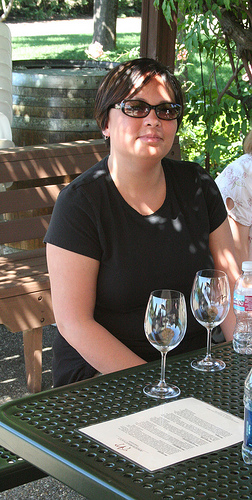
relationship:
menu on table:
[78, 393, 244, 477] [0, 333, 251, 497]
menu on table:
[78, 393, 244, 477] [52, 378, 113, 440]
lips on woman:
[138, 133, 173, 148] [50, 65, 231, 397]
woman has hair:
[46, 56, 249, 370] [93, 53, 186, 129]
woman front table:
[46, 56, 249, 370] [0, 333, 251, 497]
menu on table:
[146, 342, 243, 398] [0, 333, 251, 497]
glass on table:
[142, 288, 188, 401] [0, 333, 251, 497]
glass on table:
[189, 269, 230, 370] [0, 333, 251, 497]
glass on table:
[102, 81, 198, 119] [13, 119, 245, 363]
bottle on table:
[232, 260, 251, 355] [0, 333, 251, 497]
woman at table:
[46, 56, 249, 370] [0, 333, 251, 497]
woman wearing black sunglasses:
[46, 56, 249, 370] [111, 98, 182, 120]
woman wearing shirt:
[46, 56, 249, 370] [40, 151, 231, 349]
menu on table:
[78, 393, 244, 477] [212, 349, 230, 364]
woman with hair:
[46, 56, 247, 386] [93, 57, 184, 148]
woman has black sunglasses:
[46, 56, 249, 370] [111, 98, 182, 120]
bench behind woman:
[0, 133, 180, 394] [41, 56, 243, 389]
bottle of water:
[232, 260, 252, 355] [233, 256, 251, 370]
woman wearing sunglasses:
[46, 56, 249, 370] [110, 99, 185, 120]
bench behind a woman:
[0, 133, 180, 394] [46, 56, 249, 370]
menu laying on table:
[78, 393, 244, 477] [0, 333, 251, 497]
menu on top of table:
[78, 393, 244, 477] [0, 333, 251, 497]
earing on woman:
[100, 133, 109, 141] [46, 56, 249, 370]